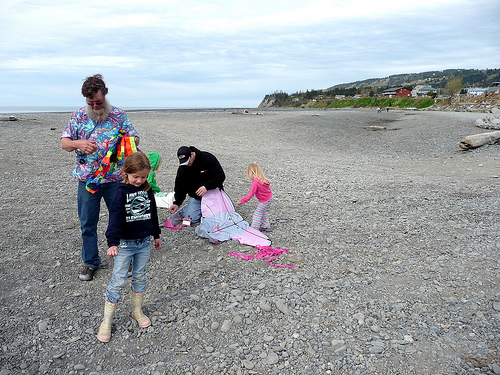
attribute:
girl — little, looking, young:
[97, 149, 166, 345]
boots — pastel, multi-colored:
[96, 291, 155, 344]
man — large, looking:
[60, 75, 142, 278]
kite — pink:
[81, 134, 137, 192]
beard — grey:
[84, 100, 113, 125]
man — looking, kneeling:
[170, 142, 232, 223]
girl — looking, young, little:
[238, 161, 278, 230]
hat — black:
[176, 146, 199, 164]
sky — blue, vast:
[8, 0, 500, 115]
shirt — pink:
[236, 177, 271, 213]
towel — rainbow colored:
[83, 134, 141, 196]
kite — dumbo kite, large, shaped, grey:
[194, 188, 278, 249]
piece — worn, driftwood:
[457, 113, 500, 153]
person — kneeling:
[168, 145, 231, 227]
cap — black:
[175, 143, 196, 164]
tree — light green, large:
[444, 75, 465, 94]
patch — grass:
[321, 90, 431, 113]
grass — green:
[328, 90, 436, 111]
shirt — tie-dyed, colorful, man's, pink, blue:
[63, 109, 139, 181]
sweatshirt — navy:
[106, 182, 165, 246]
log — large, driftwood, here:
[461, 134, 500, 153]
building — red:
[384, 84, 411, 97]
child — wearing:
[95, 152, 164, 347]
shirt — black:
[108, 182, 160, 244]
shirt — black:
[170, 148, 226, 205]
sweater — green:
[145, 148, 160, 192]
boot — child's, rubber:
[99, 302, 117, 341]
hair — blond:
[249, 158, 270, 188]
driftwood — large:
[477, 110, 499, 127]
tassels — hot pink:
[231, 244, 296, 279]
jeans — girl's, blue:
[107, 238, 154, 303]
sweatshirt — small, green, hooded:
[147, 152, 162, 192]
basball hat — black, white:
[175, 145, 194, 165]